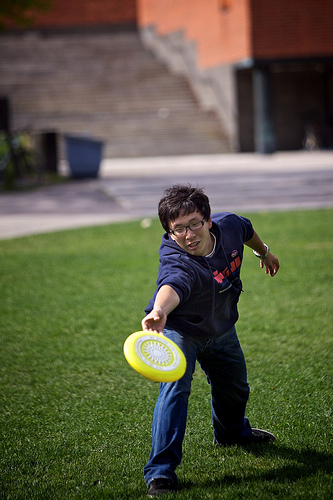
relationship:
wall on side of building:
[195, 10, 224, 36] [130, 4, 320, 152]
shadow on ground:
[183, 416, 329, 493] [0, 241, 331, 498]